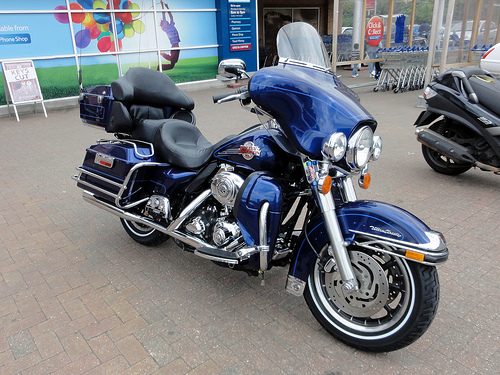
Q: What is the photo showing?
A: It is showing a store.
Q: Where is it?
A: This is at the store.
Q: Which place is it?
A: It is a store.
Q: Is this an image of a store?
A: Yes, it is showing a store.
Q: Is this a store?
A: Yes, it is a store.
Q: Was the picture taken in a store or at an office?
A: It was taken at a store.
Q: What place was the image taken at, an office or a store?
A: It was taken at a store.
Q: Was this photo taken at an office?
A: No, the picture was taken in a store.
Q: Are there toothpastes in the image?
A: No, there are no toothpastes.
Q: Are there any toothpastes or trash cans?
A: No, there are no toothpastes or trash cans.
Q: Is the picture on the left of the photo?
A: Yes, the picture is on the left of the image.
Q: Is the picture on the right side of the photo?
A: No, the picture is on the left of the image.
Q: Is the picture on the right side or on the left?
A: The picture is on the left of the image.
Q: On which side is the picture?
A: The picture is on the left of the image.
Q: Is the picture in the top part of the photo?
A: Yes, the picture is in the top of the image.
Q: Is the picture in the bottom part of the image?
A: No, the picture is in the top of the image.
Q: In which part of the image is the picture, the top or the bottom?
A: The picture is in the top of the image.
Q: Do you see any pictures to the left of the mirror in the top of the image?
A: Yes, there is a picture to the left of the mirror.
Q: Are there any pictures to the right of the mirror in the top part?
A: No, the picture is to the left of the mirror.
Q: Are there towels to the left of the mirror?
A: No, there is a picture to the left of the mirror.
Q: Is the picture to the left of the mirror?
A: Yes, the picture is to the left of the mirror.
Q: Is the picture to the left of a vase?
A: No, the picture is to the left of the mirror.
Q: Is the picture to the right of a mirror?
A: No, the picture is to the left of a mirror.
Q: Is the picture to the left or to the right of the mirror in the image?
A: The picture is to the left of the mirror.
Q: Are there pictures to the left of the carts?
A: Yes, there is a picture to the left of the carts.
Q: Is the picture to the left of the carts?
A: Yes, the picture is to the left of the carts.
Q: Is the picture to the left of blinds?
A: No, the picture is to the left of the carts.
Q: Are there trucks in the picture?
A: No, there are no trucks.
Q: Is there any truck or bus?
A: No, there are no trucks or buses.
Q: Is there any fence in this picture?
A: No, there are no fences.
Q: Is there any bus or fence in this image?
A: No, there are no fences or buses.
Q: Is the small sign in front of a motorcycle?
A: Yes, the sign is in front of a motorcycle.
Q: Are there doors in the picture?
A: Yes, there are doors.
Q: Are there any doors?
A: Yes, there are doors.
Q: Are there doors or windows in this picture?
A: Yes, there are doors.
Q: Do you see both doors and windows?
A: Yes, there are both doors and windows.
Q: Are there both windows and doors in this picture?
A: Yes, there are both doors and windows.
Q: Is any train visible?
A: No, there are no trains.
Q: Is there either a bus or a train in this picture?
A: No, there are no trains or buses.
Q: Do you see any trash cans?
A: No, there are no trash cans.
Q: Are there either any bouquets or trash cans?
A: No, there are no trash cans or bouquets.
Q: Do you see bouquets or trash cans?
A: No, there are no trash cans or bouquets.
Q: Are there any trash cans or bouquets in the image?
A: No, there are no trash cans or bouquets.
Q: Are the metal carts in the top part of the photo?
A: Yes, the carts are in the top of the image.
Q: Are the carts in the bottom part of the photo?
A: No, the carts are in the top of the image.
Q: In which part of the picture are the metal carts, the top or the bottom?
A: The carts are in the top of the image.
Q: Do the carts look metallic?
A: Yes, the carts are metallic.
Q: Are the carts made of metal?
A: Yes, the carts are made of metal.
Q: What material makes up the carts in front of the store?
A: The carts are made of metal.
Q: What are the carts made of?
A: The carts are made of metal.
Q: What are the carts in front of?
A: The carts are in front of the store.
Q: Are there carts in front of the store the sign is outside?
A: Yes, there are carts in front of the store.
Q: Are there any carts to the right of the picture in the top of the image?
A: Yes, there are carts to the right of the picture.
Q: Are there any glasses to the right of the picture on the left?
A: No, there are carts to the right of the picture.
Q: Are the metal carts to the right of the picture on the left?
A: Yes, the carts are to the right of the picture.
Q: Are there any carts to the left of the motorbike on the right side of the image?
A: Yes, there are carts to the left of the motorcycle.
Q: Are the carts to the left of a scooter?
A: No, the carts are to the left of the motorcycle.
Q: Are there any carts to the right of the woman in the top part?
A: Yes, there are carts to the right of the woman.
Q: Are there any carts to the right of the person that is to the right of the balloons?
A: Yes, there are carts to the right of the woman.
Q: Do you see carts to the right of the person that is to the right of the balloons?
A: Yes, there are carts to the right of the woman.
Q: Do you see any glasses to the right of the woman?
A: No, there are carts to the right of the woman.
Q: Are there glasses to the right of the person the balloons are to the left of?
A: No, there are carts to the right of the woman.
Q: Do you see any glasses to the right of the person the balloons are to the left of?
A: No, there are carts to the right of the woman.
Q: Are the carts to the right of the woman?
A: Yes, the carts are to the right of the woman.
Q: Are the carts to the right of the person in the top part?
A: Yes, the carts are to the right of the woman.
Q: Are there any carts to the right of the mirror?
A: Yes, there are carts to the right of the mirror.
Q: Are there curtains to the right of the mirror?
A: No, there are carts to the right of the mirror.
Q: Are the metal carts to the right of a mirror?
A: Yes, the carts are to the right of a mirror.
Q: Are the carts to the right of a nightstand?
A: No, the carts are to the right of a mirror.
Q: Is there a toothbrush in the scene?
A: No, there are no toothbrushes.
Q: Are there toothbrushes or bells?
A: No, there are no toothbrushes or bells.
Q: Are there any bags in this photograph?
A: No, there are no bags.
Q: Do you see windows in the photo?
A: Yes, there is a window.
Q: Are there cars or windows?
A: Yes, there is a window.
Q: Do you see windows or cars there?
A: Yes, there is a window.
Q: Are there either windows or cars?
A: Yes, there is a window.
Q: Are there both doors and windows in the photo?
A: Yes, there are both a window and a door.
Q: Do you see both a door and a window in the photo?
A: Yes, there are both a window and a door.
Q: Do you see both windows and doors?
A: Yes, there are both a window and a door.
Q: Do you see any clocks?
A: No, there are no clocks.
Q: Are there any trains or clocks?
A: No, there are no clocks or trains.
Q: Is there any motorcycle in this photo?
A: Yes, there is a motorcycle.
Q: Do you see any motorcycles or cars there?
A: Yes, there is a motorcycle.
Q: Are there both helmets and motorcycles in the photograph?
A: No, there is a motorcycle but no helmets.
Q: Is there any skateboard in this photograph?
A: No, there are no skateboards.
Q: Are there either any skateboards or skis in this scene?
A: No, there are no skateboards or skis.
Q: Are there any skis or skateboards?
A: No, there are no skateboards or skis.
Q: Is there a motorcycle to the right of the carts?
A: Yes, there is a motorcycle to the right of the carts.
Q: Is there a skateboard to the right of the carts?
A: No, there is a motorcycle to the right of the carts.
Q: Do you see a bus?
A: No, there are no buses.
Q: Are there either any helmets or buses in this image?
A: No, there are no buses or helmets.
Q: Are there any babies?
A: No, there are no babies.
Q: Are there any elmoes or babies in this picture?
A: No, there are no babies or elmoes.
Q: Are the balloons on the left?
A: Yes, the balloons are on the left of the image.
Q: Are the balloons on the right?
A: No, the balloons are on the left of the image.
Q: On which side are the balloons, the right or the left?
A: The balloons are on the left of the image.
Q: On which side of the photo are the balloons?
A: The balloons are on the left of the image.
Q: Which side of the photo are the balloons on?
A: The balloons are on the left of the image.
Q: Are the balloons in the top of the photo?
A: Yes, the balloons are in the top of the image.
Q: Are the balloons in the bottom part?
A: No, the balloons are in the top of the image.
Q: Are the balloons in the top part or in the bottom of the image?
A: The balloons are in the top of the image.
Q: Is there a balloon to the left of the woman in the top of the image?
A: Yes, there are balloons to the left of the woman.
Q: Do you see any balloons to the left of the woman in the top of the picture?
A: Yes, there are balloons to the left of the woman.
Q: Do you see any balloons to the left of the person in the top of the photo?
A: Yes, there are balloons to the left of the woman.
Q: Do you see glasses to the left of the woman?
A: No, there are balloons to the left of the woman.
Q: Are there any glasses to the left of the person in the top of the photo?
A: No, there are balloons to the left of the woman.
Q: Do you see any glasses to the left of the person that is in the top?
A: No, there are balloons to the left of the woman.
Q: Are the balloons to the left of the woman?
A: Yes, the balloons are to the left of the woman.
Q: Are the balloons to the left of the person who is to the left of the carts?
A: Yes, the balloons are to the left of the woman.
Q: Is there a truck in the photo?
A: No, there are no trucks.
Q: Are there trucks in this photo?
A: No, there are no trucks.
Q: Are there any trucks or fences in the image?
A: No, there are no trucks or fences.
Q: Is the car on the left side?
A: No, the car is on the right of the image.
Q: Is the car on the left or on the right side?
A: The car is on the right of the image.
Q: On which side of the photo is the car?
A: The car is on the right of the image.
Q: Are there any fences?
A: No, there are no fences.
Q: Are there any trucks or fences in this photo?
A: No, there are no fences or trucks.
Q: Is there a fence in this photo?
A: No, there are no fences.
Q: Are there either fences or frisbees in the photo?
A: No, there are no fences or frisbees.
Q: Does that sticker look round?
A: Yes, the sticker is round.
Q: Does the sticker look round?
A: Yes, the sticker is round.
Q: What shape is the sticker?
A: The sticker is round.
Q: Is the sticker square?
A: No, the sticker is round.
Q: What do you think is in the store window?
A: The sticker is in the window.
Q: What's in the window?
A: The sticker is in the window.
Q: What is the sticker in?
A: The sticker is in the window.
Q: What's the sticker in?
A: The sticker is in the window.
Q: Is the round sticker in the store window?
A: Yes, the sticker is in the window.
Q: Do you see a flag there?
A: No, there are no flags.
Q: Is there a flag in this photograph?
A: No, there are no flags.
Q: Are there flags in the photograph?
A: No, there are no flags.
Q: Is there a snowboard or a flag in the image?
A: No, there are no flags or snowboards.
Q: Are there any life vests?
A: No, there are no life vests.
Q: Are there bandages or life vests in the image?
A: No, there are no life vests or bandages.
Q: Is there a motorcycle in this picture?
A: Yes, there is a motorcycle.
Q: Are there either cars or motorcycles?
A: Yes, there is a motorcycle.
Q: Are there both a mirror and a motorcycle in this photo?
A: Yes, there are both a motorcycle and a mirror.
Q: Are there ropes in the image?
A: No, there are no ropes.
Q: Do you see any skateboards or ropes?
A: No, there are no ropes or skateboards.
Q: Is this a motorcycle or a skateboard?
A: This is a motorcycle.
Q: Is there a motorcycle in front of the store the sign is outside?
A: Yes, there is a motorcycle in front of the store.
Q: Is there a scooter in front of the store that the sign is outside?
A: No, there is a motorcycle in front of the store.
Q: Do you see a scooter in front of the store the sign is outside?
A: No, there is a motorcycle in front of the store.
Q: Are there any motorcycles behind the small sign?
A: Yes, there is a motorcycle behind the sign.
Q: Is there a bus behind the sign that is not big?
A: No, there is a motorcycle behind the sign.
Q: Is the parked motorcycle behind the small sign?
A: Yes, the motorcycle is behind the sign.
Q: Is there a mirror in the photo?
A: Yes, there is a mirror.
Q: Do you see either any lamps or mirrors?
A: Yes, there is a mirror.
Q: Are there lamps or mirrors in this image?
A: Yes, there is a mirror.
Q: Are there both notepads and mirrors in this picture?
A: No, there is a mirror but no notepads.